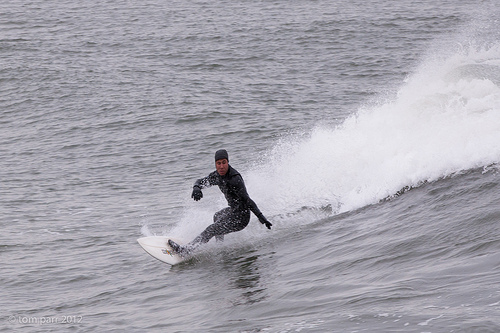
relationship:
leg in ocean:
[212, 208, 228, 244] [2, 0, 499, 331]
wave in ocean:
[169, 56, 498, 228] [2, 0, 499, 331]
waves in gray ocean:
[323, 85, 445, 191] [308, 40, 436, 148]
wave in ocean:
[7, 303, 76, 315] [2, 0, 499, 331]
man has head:
[163, 148, 272, 253] [214, 150, 231, 176]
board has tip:
[137, 232, 230, 266] [134, 236, 146, 248]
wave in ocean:
[139, 2, 498, 259] [2, 0, 499, 331]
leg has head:
[212, 208, 228, 244] [212, 147, 230, 174]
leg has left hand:
[212, 208, 228, 244] [187, 180, 221, 206]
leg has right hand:
[212, 208, 228, 244] [188, 185, 207, 201]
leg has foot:
[212, 208, 228, 244] [164, 235, 186, 252]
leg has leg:
[212, 208, 228, 244] [179, 205, 241, 260]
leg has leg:
[212, 208, 228, 244] [211, 204, 231, 244]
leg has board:
[212, 208, 228, 244] [116, 202, 230, 275]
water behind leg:
[248, 12, 493, 205] [212, 208, 228, 244]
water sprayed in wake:
[248, 12, 493, 205] [232, 103, 499, 212]